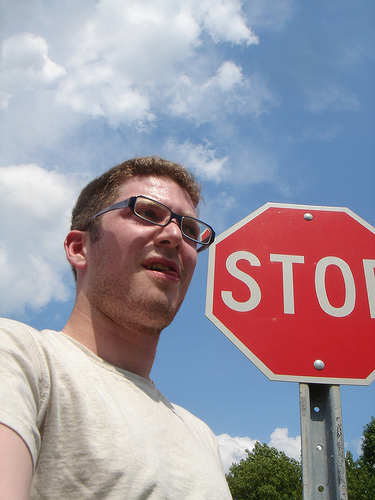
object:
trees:
[224, 414, 375, 499]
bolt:
[313, 359, 324, 370]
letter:
[220, 251, 261, 313]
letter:
[270, 253, 304, 314]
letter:
[314, 256, 355, 318]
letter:
[360, 258, 375, 318]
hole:
[314, 406, 320, 413]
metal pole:
[299, 382, 347, 498]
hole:
[316, 445, 322, 451]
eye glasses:
[86, 195, 215, 252]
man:
[0, 157, 234, 499]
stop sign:
[221, 249, 375, 319]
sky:
[1, 2, 373, 477]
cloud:
[0, 0, 365, 476]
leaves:
[252, 448, 279, 460]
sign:
[205, 202, 375, 386]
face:
[89, 177, 201, 313]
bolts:
[304, 212, 313, 220]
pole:
[298, 383, 347, 499]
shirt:
[0, 316, 233, 500]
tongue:
[162, 270, 179, 277]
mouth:
[142, 257, 179, 285]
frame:
[128, 196, 137, 210]